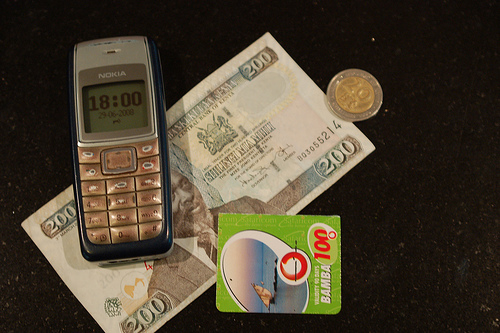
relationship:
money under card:
[18, 27, 379, 330] [212, 213, 342, 318]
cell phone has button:
[66, 30, 173, 264] [105, 176, 135, 194]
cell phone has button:
[66, 30, 173, 264] [133, 169, 160, 191]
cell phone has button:
[66, 30, 173, 264] [135, 186, 160, 208]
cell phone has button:
[66, 30, 173, 264] [135, 204, 162, 219]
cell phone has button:
[66, 30, 173, 264] [111, 224, 137, 241]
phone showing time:
[74, 32, 174, 267] [83, 87, 143, 114]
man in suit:
[148, 166, 287, 307] [146, 195, 290, 306]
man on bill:
[148, 166, 287, 307] [9, 30, 379, 332]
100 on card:
[309, 226, 334, 269] [215, 209, 345, 313]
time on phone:
[78, 86, 145, 109] [61, 29, 192, 281]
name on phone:
[92, 68, 129, 81] [58, 32, 190, 259]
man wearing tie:
[167, 166, 244, 301] [195, 235, 219, 269]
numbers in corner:
[316, 136, 363, 178] [321, 128, 373, 198]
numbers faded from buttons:
[65, 156, 215, 290] [72, 129, 226, 251]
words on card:
[316, 260, 336, 306] [215, 209, 345, 313]